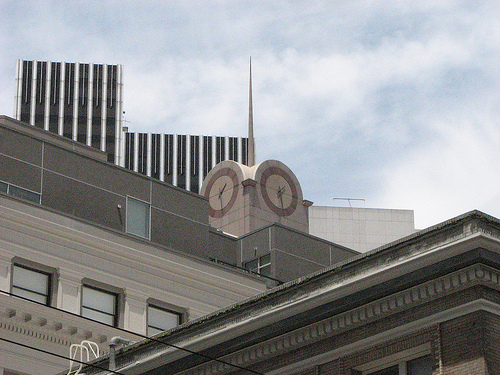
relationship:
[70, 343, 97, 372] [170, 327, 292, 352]
ladder leaning on building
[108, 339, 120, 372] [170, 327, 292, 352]
pipe near building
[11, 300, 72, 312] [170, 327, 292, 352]
wires in front of building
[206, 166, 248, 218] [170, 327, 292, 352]
clock on top of building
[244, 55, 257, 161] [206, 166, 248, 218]
spire on top of clock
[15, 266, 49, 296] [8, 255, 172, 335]
windows in a row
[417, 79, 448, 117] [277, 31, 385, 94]
sky filled with clouds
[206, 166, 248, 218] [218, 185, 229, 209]
clock on left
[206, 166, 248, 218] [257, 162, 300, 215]
clock near or clock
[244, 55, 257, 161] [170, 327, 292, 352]
pole that atop a building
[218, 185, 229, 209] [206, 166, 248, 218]
hands of clock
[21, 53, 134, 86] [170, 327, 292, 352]
top view of building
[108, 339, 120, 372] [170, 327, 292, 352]
pipe on roof of building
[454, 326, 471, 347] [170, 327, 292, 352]
brick on side of building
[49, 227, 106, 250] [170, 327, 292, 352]
paint that white on building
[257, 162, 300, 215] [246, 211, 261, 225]
clock made of bricks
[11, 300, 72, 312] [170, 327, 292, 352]
wires on side of building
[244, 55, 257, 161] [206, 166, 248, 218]
needle on top of clock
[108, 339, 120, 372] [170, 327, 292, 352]
pipe on side of building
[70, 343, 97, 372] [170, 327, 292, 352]
ladder on side of building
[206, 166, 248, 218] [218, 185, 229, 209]
clock with hand on left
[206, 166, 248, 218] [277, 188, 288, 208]
clock with hands on right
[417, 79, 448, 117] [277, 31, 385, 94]
sky with white clouds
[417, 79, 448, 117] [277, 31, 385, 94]
sky with many clouds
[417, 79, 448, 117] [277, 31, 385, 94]
sky with clouds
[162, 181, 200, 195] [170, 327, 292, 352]
edge of a building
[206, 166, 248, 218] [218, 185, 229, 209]
clock with hands on left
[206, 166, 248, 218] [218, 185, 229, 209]
clock with small hands on left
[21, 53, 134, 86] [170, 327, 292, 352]
top of building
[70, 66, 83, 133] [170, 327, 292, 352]
lines on side of building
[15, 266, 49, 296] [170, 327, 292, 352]
windows in a row on building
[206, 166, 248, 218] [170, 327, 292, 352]
clock above building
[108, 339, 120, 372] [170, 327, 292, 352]
pipe on top of building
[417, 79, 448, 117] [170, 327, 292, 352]
sky above building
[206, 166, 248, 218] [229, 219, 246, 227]
clock made of brick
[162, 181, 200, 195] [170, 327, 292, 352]
edge of building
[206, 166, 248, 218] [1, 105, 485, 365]
clock on building